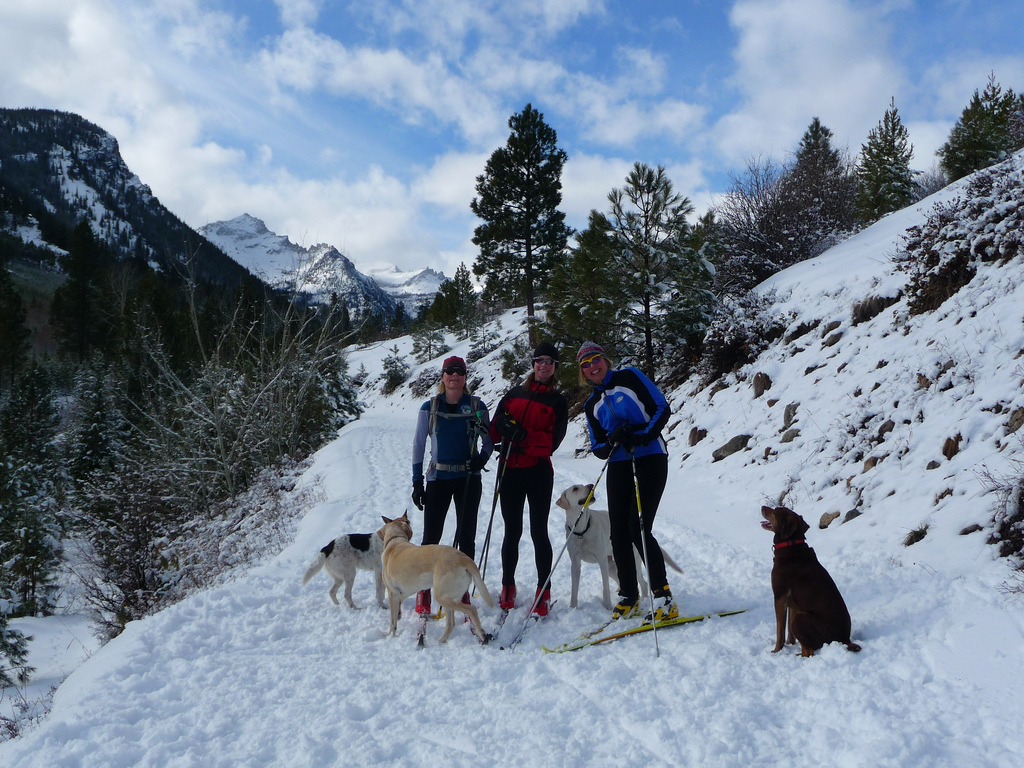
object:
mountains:
[191, 211, 470, 326]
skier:
[484, 344, 569, 618]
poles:
[480, 425, 509, 599]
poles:
[627, 444, 672, 659]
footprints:
[77, 399, 957, 763]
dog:
[376, 521, 496, 645]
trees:
[846, 93, 929, 232]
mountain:
[2, 106, 281, 313]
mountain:
[178, 211, 454, 313]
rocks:
[712, 434, 754, 461]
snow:
[2, 143, 1024, 766]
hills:
[62, 144, 1023, 768]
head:
[531, 341, 560, 378]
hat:
[531, 342, 560, 363]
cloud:
[244, 0, 764, 225]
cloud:
[693, 0, 1023, 168]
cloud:
[120, 103, 483, 289]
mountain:
[174, 212, 394, 325]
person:
[408, 354, 496, 615]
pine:
[469, 99, 580, 352]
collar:
[565, 513, 592, 539]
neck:
[566, 507, 589, 536]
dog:
[302, 509, 413, 609]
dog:
[555, 484, 684, 611]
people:
[487, 341, 571, 621]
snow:
[196, 214, 484, 322]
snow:
[0, 115, 169, 275]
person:
[573, 337, 677, 628]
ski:
[540, 607, 750, 656]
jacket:
[488, 380, 570, 469]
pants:
[498, 455, 555, 588]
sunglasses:
[445, 368, 466, 376]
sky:
[0, 0, 1022, 304]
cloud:
[0, 0, 416, 180]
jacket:
[583, 366, 672, 464]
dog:
[758, 505, 863, 657]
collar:
[775, 539, 805, 549]